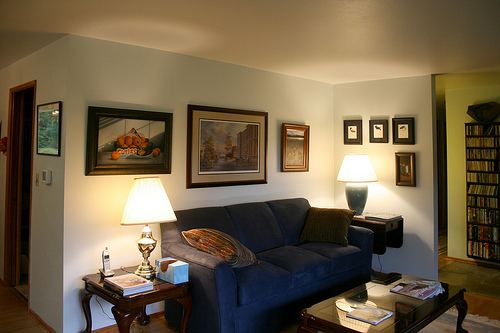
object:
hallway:
[0, 32, 64, 327]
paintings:
[200, 119, 261, 174]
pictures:
[347, 125, 358, 139]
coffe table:
[298, 272, 469, 333]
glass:
[357, 286, 383, 302]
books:
[469, 126, 473, 136]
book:
[103, 280, 153, 292]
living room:
[5, 35, 497, 332]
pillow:
[300, 207, 356, 246]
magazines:
[390, 281, 437, 300]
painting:
[96, 116, 166, 165]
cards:
[343, 120, 362, 145]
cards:
[369, 119, 389, 143]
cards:
[392, 117, 415, 145]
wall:
[329, 70, 420, 109]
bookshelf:
[464, 122, 500, 261]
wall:
[440, 70, 495, 95]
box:
[155, 257, 189, 285]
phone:
[101, 247, 111, 274]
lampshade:
[120, 177, 177, 226]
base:
[136, 226, 158, 277]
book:
[103, 283, 153, 297]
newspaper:
[404, 280, 440, 299]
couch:
[160, 197, 375, 332]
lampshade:
[337, 153, 379, 182]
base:
[345, 184, 368, 215]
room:
[4, 2, 498, 331]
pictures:
[287, 129, 305, 167]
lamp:
[121, 178, 178, 225]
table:
[84, 265, 194, 333]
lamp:
[337, 154, 379, 183]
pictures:
[373, 124, 384, 139]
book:
[466, 126, 469, 136]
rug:
[440, 318, 453, 331]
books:
[468, 241, 472, 256]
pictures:
[397, 124, 409, 139]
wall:
[31, 223, 55, 288]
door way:
[5, 78, 35, 304]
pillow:
[181, 228, 261, 268]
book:
[104, 273, 153, 290]